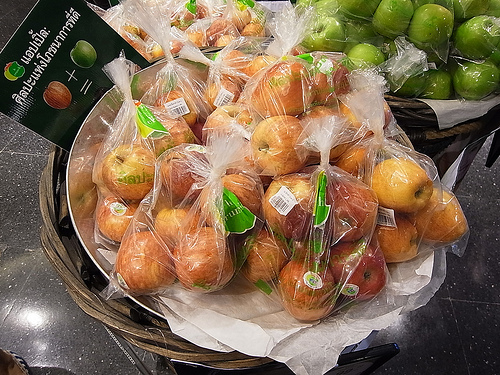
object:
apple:
[299, 16, 345, 53]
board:
[0, 2, 150, 152]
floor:
[2, 108, 496, 371]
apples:
[114, 229, 175, 296]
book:
[2, 0, 129, 127]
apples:
[104, 229, 178, 293]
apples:
[174, 225, 237, 295]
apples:
[375, 204, 417, 265]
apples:
[380, 54, 431, 96]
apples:
[451, 58, 498, 101]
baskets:
[378, 70, 498, 204]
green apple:
[453, 11, 498, 58]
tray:
[63, 45, 408, 323]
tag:
[269, 191, 300, 216]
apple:
[426, 69, 453, 101]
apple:
[347, 42, 388, 73]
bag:
[263, 128, 388, 327]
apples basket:
[38, 46, 467, 373]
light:
[9, 297, 51, 340]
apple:
[243, 112, 317, 177]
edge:
[36, 159, 82, 303]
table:
[1, 101, 498, 373]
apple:
[405, 3, 452, 51]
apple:
[369, 0, 415, 39]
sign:
[0, 2, 185, 136]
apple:
[454, 55, 498, 100]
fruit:
[121, 232, 171, 292]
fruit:
[175, 224, 227, 295]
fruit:
[244, 234, 280, 279]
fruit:
[250, 113, 308, 170]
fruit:
[374, 150, 430, 207]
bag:
[79, 57, 201, 254]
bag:
[97, 122, 278, 301]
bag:
[237, 6, 339, 125]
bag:
[125, 2, 203, 114]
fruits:
[153, 144, 212, 201]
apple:
[404, 187, 467, 242]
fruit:
[100, 141, 161, 205]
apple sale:
[66, 32, 486, 326]